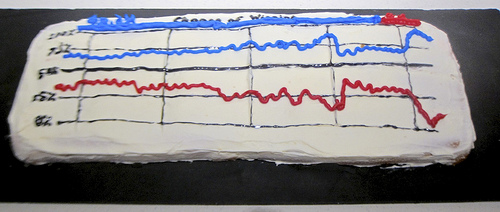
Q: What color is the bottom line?
A: Red.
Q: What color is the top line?
A: Blue.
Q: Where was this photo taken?
A: At a celebration.